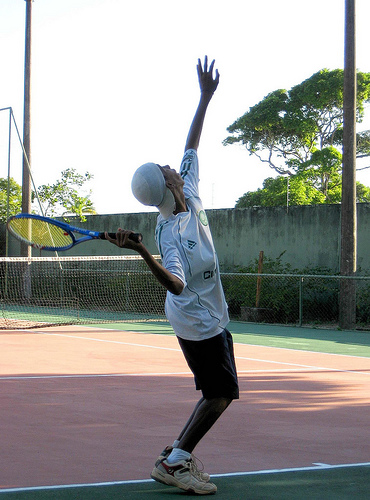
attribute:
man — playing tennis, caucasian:
[103, 52, 241, 483]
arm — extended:
[182, 57, 225, 179]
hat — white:
[128, 160, 180, 220]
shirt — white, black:
[165, 146, 230, 341]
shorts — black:
[178, 328, 240, 396]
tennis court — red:
[2, 267, 367, 498]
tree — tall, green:
[233, 70, 366, 208]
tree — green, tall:
[0, 164, 96, 221]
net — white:
[8, 255, 180, 325]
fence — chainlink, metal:
[2, 261, 367, 332]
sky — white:
[0, 0, 360, 218]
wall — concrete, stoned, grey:
[0, 207, 365, 318]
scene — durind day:
[0, 0, 365, 499]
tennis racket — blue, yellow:
[4, 210, 142, 251]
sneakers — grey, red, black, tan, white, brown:
[151, 457, 216, 498]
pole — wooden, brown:
[21, 0, 33, 303]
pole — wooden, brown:
[338, 0, 365, 331]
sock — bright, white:
[167, 446, 197, 465]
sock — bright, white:
[167, 437, 181, 449]